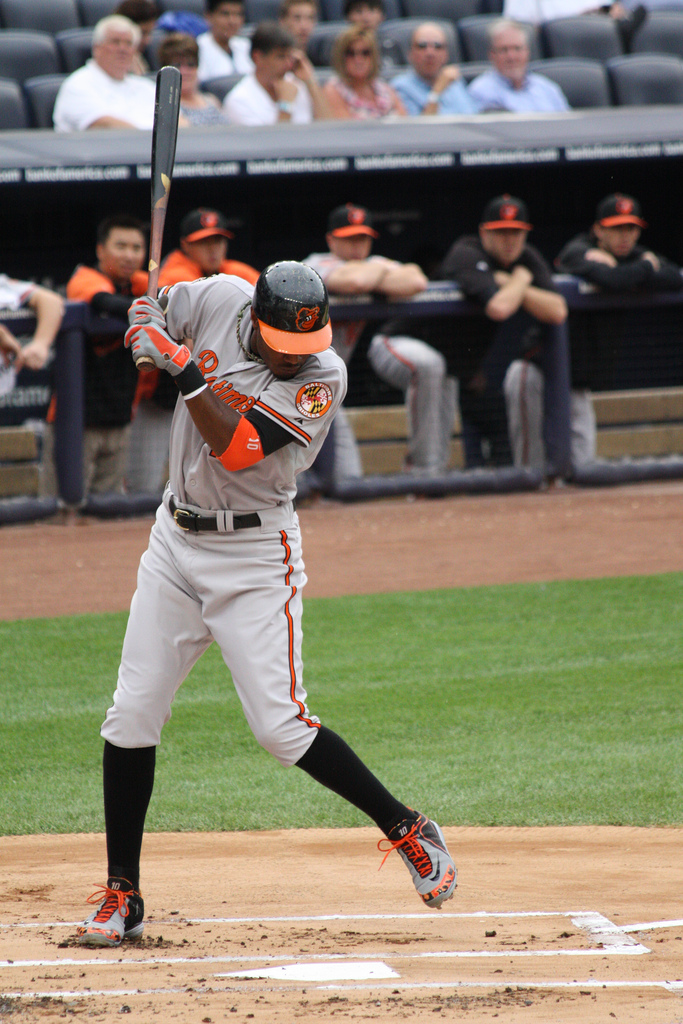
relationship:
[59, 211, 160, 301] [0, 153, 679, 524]
player watching from dugout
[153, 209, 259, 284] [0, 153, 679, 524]
player watching from dugout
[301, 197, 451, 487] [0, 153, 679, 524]
player watching from dugout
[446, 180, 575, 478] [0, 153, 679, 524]
player watching from dugout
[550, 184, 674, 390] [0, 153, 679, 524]
player watching from dugout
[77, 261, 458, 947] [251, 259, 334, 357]
man wearing helmet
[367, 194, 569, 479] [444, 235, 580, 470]
player wearing uniform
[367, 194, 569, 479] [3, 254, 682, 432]
player leaning on fence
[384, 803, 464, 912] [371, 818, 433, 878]
cleat has laces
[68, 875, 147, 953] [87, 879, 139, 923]
cleat has laces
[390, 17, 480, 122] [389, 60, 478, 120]
man wearing shirt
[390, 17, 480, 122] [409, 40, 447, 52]
man wearing sunglasses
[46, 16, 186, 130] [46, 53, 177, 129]
man wearing shirt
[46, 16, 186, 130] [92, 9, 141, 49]
man has hair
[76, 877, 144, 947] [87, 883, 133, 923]
cleat has laces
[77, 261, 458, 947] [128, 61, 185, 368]
man swinging bat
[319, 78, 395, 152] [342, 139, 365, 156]
woman wearing sunglasses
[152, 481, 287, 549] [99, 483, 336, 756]
belt holding pants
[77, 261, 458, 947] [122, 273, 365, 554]
man wearing shirt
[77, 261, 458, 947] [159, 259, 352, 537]
man wearing shirt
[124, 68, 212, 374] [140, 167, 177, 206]
bat with star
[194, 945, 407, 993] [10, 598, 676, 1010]
plate on ground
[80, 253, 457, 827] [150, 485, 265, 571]
man wearing belt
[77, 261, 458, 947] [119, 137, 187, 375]
man holding bat